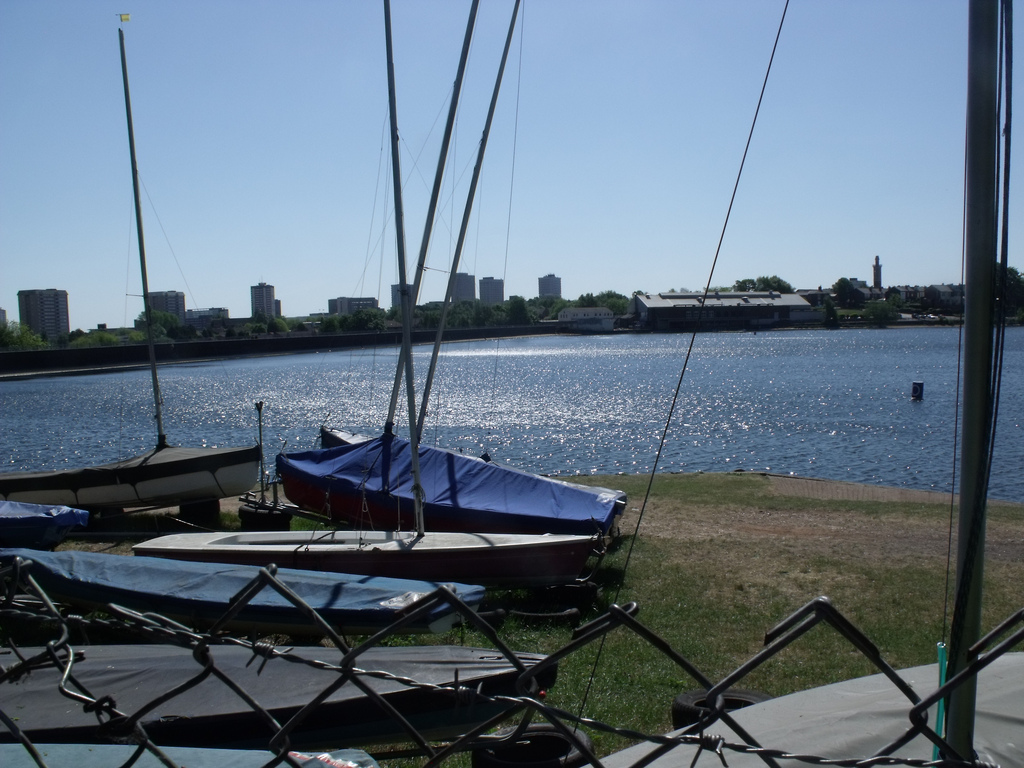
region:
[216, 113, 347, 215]
white clouds in blue sky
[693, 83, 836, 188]
white clouds in blue sky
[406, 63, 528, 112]
white clouds in blue sky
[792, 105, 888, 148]
white clouds in the blue sky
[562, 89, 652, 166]
a view of sky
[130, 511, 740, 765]
a view of fence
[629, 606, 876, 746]
a view of iron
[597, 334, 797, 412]
a view of water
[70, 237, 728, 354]
a view of buidings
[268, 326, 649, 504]
sun shine in water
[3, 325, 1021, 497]
the water is glistening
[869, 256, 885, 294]
the tower on the other side on the water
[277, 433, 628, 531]
the blue tarp on the boat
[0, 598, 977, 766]
the barbed wire on the fence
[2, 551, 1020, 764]
the chain link fence with barbed wire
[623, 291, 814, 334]
the building on the otherside of the water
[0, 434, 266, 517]
the boat with the brown cover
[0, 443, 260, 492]
the brown cover on the white boat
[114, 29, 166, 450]
the mast of the white boat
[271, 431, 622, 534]
small boat on green grass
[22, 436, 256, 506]
small boat on green grass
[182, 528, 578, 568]
small boat on green grass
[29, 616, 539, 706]
small boat on green grass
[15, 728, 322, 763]
small boat on green grass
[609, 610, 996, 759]
small boat on green grass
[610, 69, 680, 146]
white clouds in blue sky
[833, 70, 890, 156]
white clouds in blue sky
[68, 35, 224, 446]
Tall mast on the boat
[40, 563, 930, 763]
Fence on the edge of all the boats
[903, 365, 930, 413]
Wooden post com8ng out of the water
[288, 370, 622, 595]
Blue cover on top of the boat.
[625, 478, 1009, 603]
Brown dirt and grass near the edge of the water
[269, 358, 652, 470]
Water glistening in the sunlight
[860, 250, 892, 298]
Tall steeple in the distance on the other side of the water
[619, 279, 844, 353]
Long building on the other end of the water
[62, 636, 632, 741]
Barbed wire next to the chain link fence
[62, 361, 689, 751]
Several sailboats on the shore next to the water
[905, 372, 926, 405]
Buoy in water.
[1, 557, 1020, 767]
Fence in front of boats.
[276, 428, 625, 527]
Blue cover over boat.